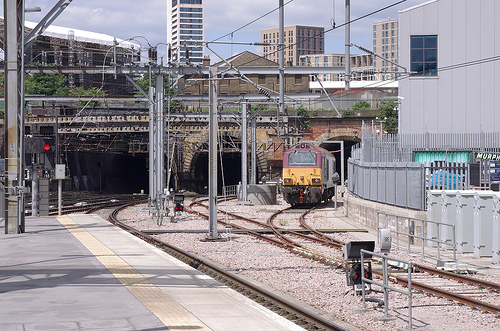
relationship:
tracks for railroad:
[117, 185, 500, 329] [5, 3, 496, 327]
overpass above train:
[18, 106, 399, 190] [283, 139, 338, 205]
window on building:
[409, 32, 442, 79] [395, 1, 499, 149]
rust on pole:
[8, 122, 20, 178] [3, 1, 29, 233]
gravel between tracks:
[118, 188, 498, 325] [117, 185, 500, 329]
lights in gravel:
[346, 268, 373, 284] [118, 188, 498, 325]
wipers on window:
[289, 152, 319, 162] [286, 148, 319, 167]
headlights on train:
[283, 178, 319, 183] [283, 139, 338, 205]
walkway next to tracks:
[2, 212, 311, 328] [117, 185, 500, 329]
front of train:
[281, 141, 329, 205] [283, 139, 338, 205]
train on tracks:
[283, 139, 338, 205] [117, 185, 500, 329]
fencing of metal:
[346, 122, 498, 212] [346, 119, 499, 212]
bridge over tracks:
[18, 106, 399, 190] [117, 185, 500, 329]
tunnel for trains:
[180, 128, 375, 203] [280, 137, 344, 204]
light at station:
[44, 141, 53, 153] [3, 130, 305, 329]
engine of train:
[282, 141, 340, 207] [283, 139, 338, 205]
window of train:
[286, 148, 319, 167] [283, 139, 338, 205]